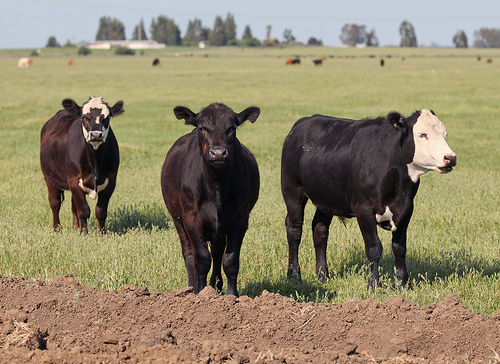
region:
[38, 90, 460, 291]
three cows standing in a field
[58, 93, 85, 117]
the ear of a cow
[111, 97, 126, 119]
the ear of a cow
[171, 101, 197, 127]
the ear of a cow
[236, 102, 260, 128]
the ear of a cow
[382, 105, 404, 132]
the ear of a cow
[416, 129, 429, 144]
the eye of a cow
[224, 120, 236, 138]
the eye of a cow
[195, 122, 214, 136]
the eye of a cow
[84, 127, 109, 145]
the nose of a cow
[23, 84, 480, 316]
three cows three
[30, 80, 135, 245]
fyi: i have seen a similar cow referred to as 'KISS groupie'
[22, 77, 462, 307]
angus, hereford, black hereford, or black baldy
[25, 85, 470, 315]
black baldy & black hereford are hereford/angus hybrids. cf left & right, middle is probably angus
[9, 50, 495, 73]
a long thin meandering of cows in the distance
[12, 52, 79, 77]
these two seem even brown+white: plain herefords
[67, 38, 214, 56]
a low flat building behind the distant cows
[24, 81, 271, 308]
two cows confront photographer w/ not particularly pleasant expressions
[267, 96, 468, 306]
rightmost cow has cowpacetic countenance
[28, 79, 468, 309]
catching rays, positively posing, on longish grass before dirtlike dirt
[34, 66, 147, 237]
a cow with white abd brown face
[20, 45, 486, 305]
three cows in a field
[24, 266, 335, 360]
a dirt patch in the field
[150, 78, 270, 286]
a mean looking cow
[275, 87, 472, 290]
a cow with a white face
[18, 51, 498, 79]
more animals in the distance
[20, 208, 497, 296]
green grass grows in the field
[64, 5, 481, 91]
trees line the back of the field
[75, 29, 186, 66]
a white building on the horizon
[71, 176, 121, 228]
cows have odd knees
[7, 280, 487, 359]
dirt on the ground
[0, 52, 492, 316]
large green grassy field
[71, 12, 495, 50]
tall trees on the horizon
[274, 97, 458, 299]
a black cow with a white head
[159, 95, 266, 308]
a black cow looking at the camera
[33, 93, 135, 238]
a dark brown cow with a spotted white head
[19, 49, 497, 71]
cows grazing in the background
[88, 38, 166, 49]
a white building in the distance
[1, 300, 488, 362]
dirt road next to the field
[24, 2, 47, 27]
white clouds in blue sky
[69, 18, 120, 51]
white clouds in blue sky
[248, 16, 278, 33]
white clouds in blue sky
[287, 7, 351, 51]
white clouds in blue sky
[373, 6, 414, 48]
white clouds in blue sky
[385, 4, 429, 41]
white clouds in blue sky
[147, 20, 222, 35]
white clouds in blue sky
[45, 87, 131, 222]
black and white cow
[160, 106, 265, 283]
black and white cow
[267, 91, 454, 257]
black and white cow